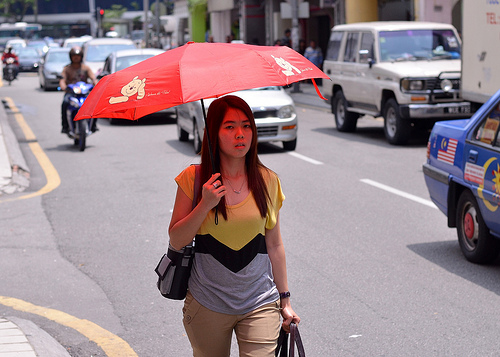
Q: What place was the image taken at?
A: It was taken at the road.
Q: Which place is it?
A: It is a road.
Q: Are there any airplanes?
A: No, there are no airplanes.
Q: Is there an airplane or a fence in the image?
A: No, there are no airplanes or fences.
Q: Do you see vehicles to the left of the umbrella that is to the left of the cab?
A: Yes, there is a vehicle to the left of the umbrella.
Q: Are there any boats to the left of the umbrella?
A: No, there is a vehicle to the left of the umbrella.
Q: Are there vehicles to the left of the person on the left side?
A: Yes, there is a vehicle to the left of the person.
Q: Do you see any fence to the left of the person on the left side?
A: No, there is a vehicle to the left of the person.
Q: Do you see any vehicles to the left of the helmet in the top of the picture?
A: Yes, there is a vehicle to the left of the helmet.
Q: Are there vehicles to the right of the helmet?
A: No, the vehicle is to the left of the helmet.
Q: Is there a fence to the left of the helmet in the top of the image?
A: No, there is a vehicle to the left of the helmet.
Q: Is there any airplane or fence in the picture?
A: No, there are no fences or airplanes.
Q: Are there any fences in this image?
A: No, there are no fences.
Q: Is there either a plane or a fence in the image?
A: No, there are no fences or airplanes.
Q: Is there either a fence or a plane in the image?
A: No, there are no fences or airplanes.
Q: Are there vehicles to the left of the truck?
A: Yes, there is a vehicle to the left of the truck.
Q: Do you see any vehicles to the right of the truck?
A: No, the vehicle is to the left of the truck.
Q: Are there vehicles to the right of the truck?
A: No, the vehicle is to the left of the truck.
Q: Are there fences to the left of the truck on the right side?
A: No, there is a vehicle to the left of the truck.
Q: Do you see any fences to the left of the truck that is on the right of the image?
A: No, there is a vehicle to the left of the truck.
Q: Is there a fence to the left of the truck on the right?
A: No, there is a vehicle to the left of the truck.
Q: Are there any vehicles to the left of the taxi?
A: Yes, there is a vehicle to the left of the taxi.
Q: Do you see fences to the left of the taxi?
A: No, there is a vehicle to the left of the taxi.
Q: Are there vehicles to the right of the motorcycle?
A: Yes, there is a vehicle to the right of the motorcycle.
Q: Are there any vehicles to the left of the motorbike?
A: No, the vehicle is to the right of the motorbike.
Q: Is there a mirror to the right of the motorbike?
A: No, there is a vehicle to the right of the motorbike.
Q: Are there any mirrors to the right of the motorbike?
A: No, there is a vehicle to the right of the motorbike.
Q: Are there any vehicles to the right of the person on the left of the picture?
A: Yes, there is a vehicle to the right of the person.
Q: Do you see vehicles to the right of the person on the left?
A: Yes, there is a vehicle to the right of the person.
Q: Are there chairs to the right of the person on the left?
A: No, there is a vehicle to the right of the person.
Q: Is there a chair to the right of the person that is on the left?
A: No, there is a vehicle to the right of the person.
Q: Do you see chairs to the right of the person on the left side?
A: No, there is a vehicle to the right of the person.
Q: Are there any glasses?
A: No, there are no glasses.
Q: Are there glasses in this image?
A: No, there are no glasses.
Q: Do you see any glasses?
A: No, there are no glasses.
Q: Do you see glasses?
A: No, there are no glasses.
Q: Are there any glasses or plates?
A: No, there are no glasses or plates.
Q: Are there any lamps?
A: No, there are no lamps.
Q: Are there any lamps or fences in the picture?
A: No, there are no lamps or fences.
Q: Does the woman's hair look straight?
A: Yes, the hair is straight.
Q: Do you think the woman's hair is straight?
A: Yes, the hair is straight.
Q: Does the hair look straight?
A: Yes, the hair is straight.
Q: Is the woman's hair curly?
A: No, the hair is straight.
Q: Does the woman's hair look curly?
A: No, the hair is straight.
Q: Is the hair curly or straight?
A: The hair is straight.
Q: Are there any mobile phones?
A: No, there are no mobile phones.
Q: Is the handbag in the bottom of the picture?
A: Yes, the handbag is in the bottom of the image.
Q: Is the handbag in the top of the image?
A: No, the handbag is in the bottom of the image.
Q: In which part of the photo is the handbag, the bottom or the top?
A: The handbag is in the bottom of the image.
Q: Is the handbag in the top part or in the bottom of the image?
A: The handbag is in the bottom of the image.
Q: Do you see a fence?
A: No, there are no fences.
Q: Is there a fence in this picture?
A: No, there are no fences.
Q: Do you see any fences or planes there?
A: No, there are no fences or planes.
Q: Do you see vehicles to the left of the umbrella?
A: Yes, there is a vehicle to the left of the umbrella.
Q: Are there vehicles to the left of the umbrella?
A: Yes, there is a vehicle to the left of the umbrella.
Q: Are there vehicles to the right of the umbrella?
A: No, the vehicle is to the left of the umbrella.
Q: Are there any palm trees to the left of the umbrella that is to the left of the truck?
A: No, there is a vehicle to the left of the umbrella.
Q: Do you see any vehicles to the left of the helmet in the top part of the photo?
A: Yes, there is a vehicle to the left of the helmet.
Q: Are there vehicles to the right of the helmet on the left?
A: No, the vehicle is to the left of the helmet.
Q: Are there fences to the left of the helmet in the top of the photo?
A: No, there is a vehicle to the left of the helmet.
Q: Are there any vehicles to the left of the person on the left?
A: Yes, there is a vehicle to the left of the person.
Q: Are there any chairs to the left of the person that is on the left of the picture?
A: No, there is a vehicle to the left of the person.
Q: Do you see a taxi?
A: Yes, there is a taxi.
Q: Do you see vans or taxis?
A: Yes, there is a taxi.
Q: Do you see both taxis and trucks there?
A: Yes, there are both a taxi and a truck.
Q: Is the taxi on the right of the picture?
A: Yes, the taxi is on the right of the image.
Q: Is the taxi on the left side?
A: No, the taxi is on the right of the image.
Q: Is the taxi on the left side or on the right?
A: The taxi is on the right of the image.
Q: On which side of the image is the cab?
A: The cab is on the right of the image.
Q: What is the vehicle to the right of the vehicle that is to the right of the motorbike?
A: The vehicle is a taxi.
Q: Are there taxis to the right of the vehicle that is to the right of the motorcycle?
A: Yes, there is a taxi to the right of the vehicle.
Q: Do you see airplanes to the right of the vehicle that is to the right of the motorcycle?
A: No, there is a taxi to the right of the vehicle.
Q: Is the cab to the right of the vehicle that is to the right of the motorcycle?
A: Yes, the cab is to the right of the vehicle.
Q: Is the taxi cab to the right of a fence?
A: No, the taxi cab is to the right of the vehicle.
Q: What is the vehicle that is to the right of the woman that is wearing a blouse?
A: The vehicle is a taxi.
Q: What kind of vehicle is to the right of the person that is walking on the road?
A: The vehicle is a taxi.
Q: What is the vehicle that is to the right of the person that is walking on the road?
A: The vehicle is a taxi.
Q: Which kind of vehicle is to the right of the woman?
A: The vehicle is a taxi.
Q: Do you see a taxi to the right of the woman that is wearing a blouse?
A: Yes, there is a taxi to the right of the woman.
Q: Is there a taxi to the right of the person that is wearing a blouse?
A: Yes, there is a taxi to the right of the woman.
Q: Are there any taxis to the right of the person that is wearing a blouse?
A: Yes, there is a taxi to the right of the woman.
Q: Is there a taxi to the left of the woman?
A: No, the taxi is to the right of the woman.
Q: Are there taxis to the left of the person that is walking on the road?
A: No, the taxi is to the right of the woman.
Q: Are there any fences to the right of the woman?
A: No, there is a taxi to the right of the woman.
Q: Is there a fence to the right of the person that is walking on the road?
A: No, there is a taxi to the right of the woman.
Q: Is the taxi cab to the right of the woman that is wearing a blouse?
A: Yes, the taxi cab is to the right of the woman.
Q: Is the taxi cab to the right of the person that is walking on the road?
A: Yes, the taxi cab is to the right of the woman.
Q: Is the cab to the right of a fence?
A: No, the cab is to the right of the woman.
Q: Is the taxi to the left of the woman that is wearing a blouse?
A: No, the taxi is to the right of the woman.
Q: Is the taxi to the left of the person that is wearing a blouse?
A: No, the taxi is to the right of the woman.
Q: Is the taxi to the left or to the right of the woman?
A: The taxi is to the right of the woman.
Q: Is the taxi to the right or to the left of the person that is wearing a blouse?
A: The taxi is to the right of the woman.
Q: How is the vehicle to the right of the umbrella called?
A: The vehicle is a taxi.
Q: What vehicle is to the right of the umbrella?
A: The vehicle is a taxi.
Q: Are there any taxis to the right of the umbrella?
A: Yes, there is a taxi to the right of the umbrella.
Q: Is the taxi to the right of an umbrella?
A: Yes, the taxi is to the right of an umbrella.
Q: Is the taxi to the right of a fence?
A: No, the taxi is to the right of an umbrella.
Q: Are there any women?
A: Yes, there is a woman.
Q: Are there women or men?
A: Yes, there is a woman.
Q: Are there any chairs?
A: No, there are no chairs.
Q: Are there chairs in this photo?
A: No, there are no chairs.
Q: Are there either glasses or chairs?
A: No, there are no chairs or glasses.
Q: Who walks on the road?
A: The woman walks on the road.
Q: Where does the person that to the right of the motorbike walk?
A: The woman walks on the road.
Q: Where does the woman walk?
A: The woman walks on the road.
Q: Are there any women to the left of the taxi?
A: Yes, there is a woman to the left of the taxi.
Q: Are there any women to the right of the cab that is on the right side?
A: No, the woman is to the left of the taxi cab.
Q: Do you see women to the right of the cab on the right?
A: No, the woman is to the left of the taxi cab.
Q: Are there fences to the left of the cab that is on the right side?
A: No, there is a woman to the left of the cab.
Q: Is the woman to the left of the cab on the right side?
A: Yes, the woman is to the left of the taxi.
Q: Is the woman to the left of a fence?
A: No, the woman is to the left of the taxi.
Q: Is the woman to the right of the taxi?
A: No, the woman is to the left of the taxi.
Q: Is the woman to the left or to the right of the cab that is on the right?
A: The woman is to the left of the taxi cab.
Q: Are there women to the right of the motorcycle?
A: Yes, there is a woman to the right of the motorcycle.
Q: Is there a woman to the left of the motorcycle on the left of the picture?
A: No, the woman is to the right of the motorbike.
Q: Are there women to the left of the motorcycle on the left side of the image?
A: No, the woman is to the right of the motorbike.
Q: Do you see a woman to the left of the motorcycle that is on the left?
A: No, the woman is to the right of the motorbike.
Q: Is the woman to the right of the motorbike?
A: Yes, the woman is to the right of the motorbike.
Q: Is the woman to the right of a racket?
A: No, the woman is to the right of the motorbike.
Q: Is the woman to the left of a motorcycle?
A: No, the woman is to the right of a motorcycle.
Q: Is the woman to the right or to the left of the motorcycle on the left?
A: The woman is to the right of the motorbike.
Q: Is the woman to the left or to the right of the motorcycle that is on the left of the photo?
A: The woman is to the right of the motorbike.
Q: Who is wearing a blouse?
A: The woman is wearing a blouse.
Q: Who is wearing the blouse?
A: The woman is wearing a blouse.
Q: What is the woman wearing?
A: The woman is wearing a blouse.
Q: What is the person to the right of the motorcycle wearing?
A: The woman is wearing a blouse.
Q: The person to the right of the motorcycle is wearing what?
A: The woman is wearing a blouse.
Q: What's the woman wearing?
A: The woman is wearing a blouse.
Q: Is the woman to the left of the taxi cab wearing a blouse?
A: Yes, the woman is wearing a blouse.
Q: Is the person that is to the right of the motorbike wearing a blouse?
A: Yes, the woman is wearing a blouse.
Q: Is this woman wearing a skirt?
A: No, the woman is wearing a blouse.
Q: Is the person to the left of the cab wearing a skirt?
A: No, the woman is wearing a blouse.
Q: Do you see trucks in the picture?
A: Yes, there is a truck.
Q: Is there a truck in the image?
A: Yes, there is a truck.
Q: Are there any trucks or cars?
A: Yes, there is a truck.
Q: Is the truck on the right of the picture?
A: Yes, the truck is on the right of the image.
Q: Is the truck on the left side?
A: No, the truck is on the right of the image.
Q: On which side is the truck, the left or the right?
A: The truck is on the right of the image.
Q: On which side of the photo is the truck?
A: The truck is on the right of the image.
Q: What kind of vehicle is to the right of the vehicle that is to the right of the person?
A: The vehicle is a truck.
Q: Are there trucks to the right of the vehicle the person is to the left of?
A: Yes, there is a truck to the right of the vehicle.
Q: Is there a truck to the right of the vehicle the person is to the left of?
A: Yes, there is a truck to the right of the vehicle.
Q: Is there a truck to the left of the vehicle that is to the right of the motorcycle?
A: No, the truck is to the right of the vehicle.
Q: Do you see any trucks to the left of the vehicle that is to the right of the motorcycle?
A: No, the truck is to the right of the vehicle.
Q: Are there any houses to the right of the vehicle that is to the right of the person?
A: No, there is a truck to the right of the vehicle.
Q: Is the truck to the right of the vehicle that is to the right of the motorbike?
A: Yes, the truck is to the right of the vehicle.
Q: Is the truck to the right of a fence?
A: No, the truck is to the right of the vehicle.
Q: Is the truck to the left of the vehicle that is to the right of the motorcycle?
A: No, the truck is to the right of the vehicle.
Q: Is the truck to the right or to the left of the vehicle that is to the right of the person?
A: The truck is to the right of the vehicle.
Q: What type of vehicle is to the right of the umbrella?
A: The vehicle is a truck.